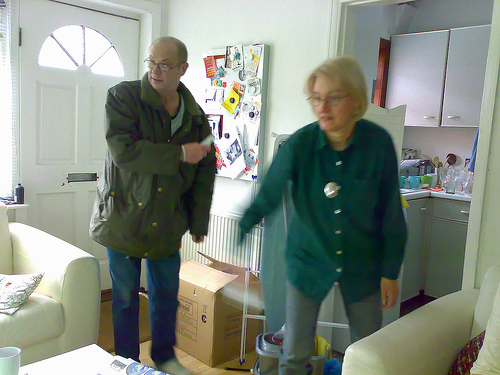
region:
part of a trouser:
[283, 301, 315, 349]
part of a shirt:
[316, 199, 367, 282]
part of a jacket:
[133, 208, 185, 271]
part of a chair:
[27, 283, 53, 313]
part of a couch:
[385, 335, 407, 357]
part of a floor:
[188, 354, 208, 366]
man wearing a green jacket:
[101, 97, 189, 240]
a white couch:
[358, 326, 427, 368]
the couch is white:
[50, 278, 100, 328]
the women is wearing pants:
[284, 280, 316, 372]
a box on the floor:
[190, 278, 232, 359]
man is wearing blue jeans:
[111, 264, 161, 359]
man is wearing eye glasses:
[143, 51, 175, 76]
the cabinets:
[413, 68, 473, 114]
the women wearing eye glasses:
[309, 91, 349, 106]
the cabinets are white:
[428, 218, 455, 268]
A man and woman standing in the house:
[79, 34, 444, 361]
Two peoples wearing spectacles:
[137, 53, 359, 115]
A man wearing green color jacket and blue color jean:
[89, 74, 225, 259]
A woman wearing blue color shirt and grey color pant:
[258, 80, 431, 366]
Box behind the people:
[184, 256, 241, 373]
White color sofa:
[2, 212, 106, 363]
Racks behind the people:
[394, 45, 485, 113]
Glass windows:
[42, 44, 124, 71]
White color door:
[27, 66, 146, 294]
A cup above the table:
[2, 342, 19, 374]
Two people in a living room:
[20, 37, 495, 372]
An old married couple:
[99, 29, 432, 373]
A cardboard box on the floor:
[151, 256, 267, 361]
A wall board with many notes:
[185, 43, 269, 183]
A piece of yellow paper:
[220, 89, 243, 117]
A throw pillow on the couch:
[0, 275, 54, 322]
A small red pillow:
[445, 334, 490, 373]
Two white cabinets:
[384, 31, 479, 128]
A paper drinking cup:
[2, 342, 29, 373]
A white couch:
[7, 221, 119, 342]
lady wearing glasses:
[251, 56, 408, 369]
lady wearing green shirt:
[256, 51, 415, 373]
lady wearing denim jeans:
[254, 55, 414, 374]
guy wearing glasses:
[91, 20, 213, 374]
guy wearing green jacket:
[103, 20, 223, 369]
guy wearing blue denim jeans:
[93, 35, 222, 356]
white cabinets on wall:
[380, 9, 494, 146]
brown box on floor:
[158, 235, 278, 372]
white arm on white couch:
[2, 200, 97, 359]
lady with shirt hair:
[289, 54, 388, 149]